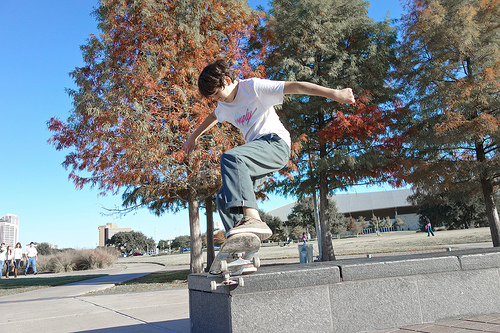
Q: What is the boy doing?
A: Skateboarding.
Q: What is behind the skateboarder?
A: Trees.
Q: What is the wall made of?
A: Stone.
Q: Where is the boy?
A: Park.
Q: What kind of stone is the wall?
A: Concrete blocks.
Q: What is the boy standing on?
A: Skateboard.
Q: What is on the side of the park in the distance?
A: House.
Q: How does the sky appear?
A: Clear.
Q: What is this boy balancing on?
A: A skateboard.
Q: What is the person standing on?
A: Surfboard.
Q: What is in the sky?
A: Clouds.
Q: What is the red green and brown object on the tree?
A: Leaves.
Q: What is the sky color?
A: Blue.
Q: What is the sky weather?
A: Clear.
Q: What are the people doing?
A: Walking.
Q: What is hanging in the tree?
A: Leaves.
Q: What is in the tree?
A: Leaves.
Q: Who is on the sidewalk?
A: Some people.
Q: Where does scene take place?
A: In a park.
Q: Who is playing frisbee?
A: A couple behind the trees.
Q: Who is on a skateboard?
A: A teenager.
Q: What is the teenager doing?
A: Tricks off a short wall.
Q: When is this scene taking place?
A: Middle of the afternoon.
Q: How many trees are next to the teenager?
A: 3.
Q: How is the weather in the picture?
A: Sunny and dry.